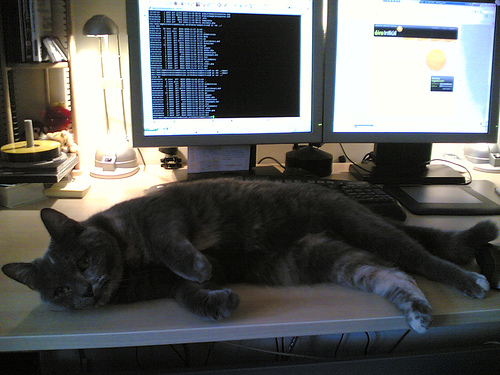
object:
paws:
[181, 250, 213, 284]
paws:
[196, 287, 241, 322]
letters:
[219, 24, 224, 26]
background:
[0, 0, 499, 374]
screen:
[138, 0, 313, 137]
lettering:
[215, 40, 221, 44]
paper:
[42, 180, 93, 198]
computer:
[322, 0, 499, 186]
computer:
[124, 0, 323, 196]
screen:
[331, 0, 498, 134]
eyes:
[77, 252, 94, 269]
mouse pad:
[383, 183, 499, 217]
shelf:
[1, 0, 81, 171]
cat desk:
[0, 159, 499, 355]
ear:
[40, 207, 82, 241]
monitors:
[123, 1, 498, 152]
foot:
[406, 303, 435, 335]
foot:
[463, 272, 490, 301]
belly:
[199, 200, 301, 287]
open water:
[77, 12, 132, 182]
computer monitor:
[123, 0, 324, 148]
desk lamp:
[81, 14, 139, 181]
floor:
[211, 129, 302, 159]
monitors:
[321, 0, 500, 144]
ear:
[0, 262, 46, 292]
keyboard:
[144, 174, 408, 224]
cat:
[0, 177, 499, 335]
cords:
[247, 340, 455, 361]